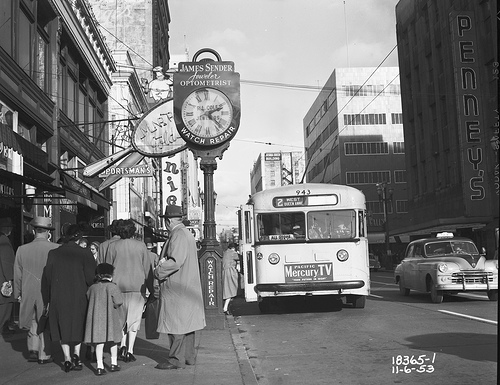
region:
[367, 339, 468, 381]
photo is from November 6, 1953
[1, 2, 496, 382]
photo is in black and white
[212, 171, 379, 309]
woman in long coat boards the bus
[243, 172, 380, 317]
bus has "Mercury TV" written in the front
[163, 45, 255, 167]
clock has roman numerals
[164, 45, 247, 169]
time on the clock reads 2:22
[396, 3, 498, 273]
building on the right has a sign that says "Penney's"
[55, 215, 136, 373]
one child in a group of adults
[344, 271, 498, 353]
white lines in the street indicate lanes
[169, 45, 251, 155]
clock features an ad for optometrist James Sender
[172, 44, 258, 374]
a clock on the sidewalk in a city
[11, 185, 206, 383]
people walking down city sidewalk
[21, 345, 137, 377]
the people are all wearing black shoes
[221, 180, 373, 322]
a woman is boarding the bus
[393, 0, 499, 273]
a multistoried building with a logo displayed out front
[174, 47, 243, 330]
the clock in the street is advertising watch repair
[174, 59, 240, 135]
the clock is advertising an optomitrist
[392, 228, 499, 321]
a taxi cab is driving down the city street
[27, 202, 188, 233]
the men are wearing hats in the city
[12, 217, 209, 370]
the crowd is wearing long coats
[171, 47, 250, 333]
a pole with a clock on top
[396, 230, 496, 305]
a taxi driving down the street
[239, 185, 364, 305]
a bus parked so it can get passengers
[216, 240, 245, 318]
a woman getting onto the bus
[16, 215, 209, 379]
a group of people walking down the street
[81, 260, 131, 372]
a young girl standing in the back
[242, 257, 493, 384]
the street the car is going down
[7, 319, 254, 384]
the sidewalk the people are standing on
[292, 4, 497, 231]
some tall buildings on the side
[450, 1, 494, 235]
the sign saying what store it is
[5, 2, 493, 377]
black and white in 1953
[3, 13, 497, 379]
black and white photo of the 1950s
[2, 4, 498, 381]
the city in 1953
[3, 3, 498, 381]
city street in the 1950s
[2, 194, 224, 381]
people walking in the city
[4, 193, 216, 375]
people in the city in black and white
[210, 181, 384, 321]
city bus in the 1950s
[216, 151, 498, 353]
cars on the street in the 1950s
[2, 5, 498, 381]
city life in the 1950s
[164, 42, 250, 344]
black and white street clock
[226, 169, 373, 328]
a bus on the street with doors open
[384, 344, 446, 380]
stamp showing 11-6-53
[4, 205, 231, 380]
a group of people on the sidewalk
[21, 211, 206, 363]
a group of people all wearing long jackets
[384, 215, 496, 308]
a car driving by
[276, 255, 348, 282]
advertisement on the front of the bus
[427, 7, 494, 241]
a long sign on building shows penney's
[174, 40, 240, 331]
a clock on a metal pole on sidewalk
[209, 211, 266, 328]
a woman getting on the bus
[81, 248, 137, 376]
a young girl wearing white tights